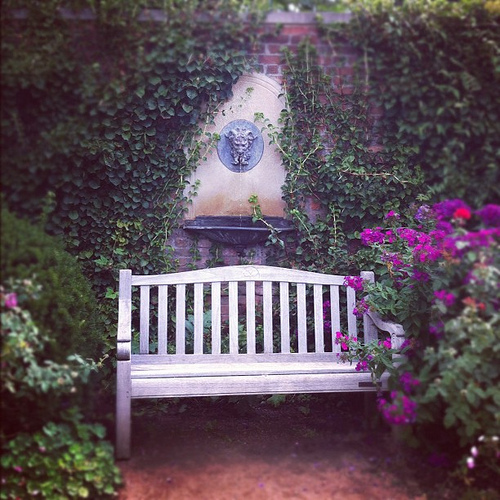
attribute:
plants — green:
[78, 60, 183, 239]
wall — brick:
[0, 8, 397, 337]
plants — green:
[1, 1, 498, 498]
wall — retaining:
[63, 27, 458, 226]